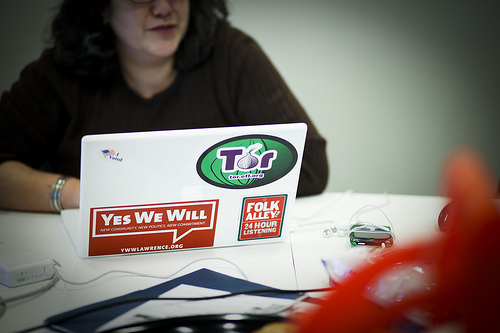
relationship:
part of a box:
[350, 231, 373, 244] [349, 229, 393, 247]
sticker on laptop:
[197, 134, 299, 189] [62, 121, 309, 259]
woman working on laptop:
[0, 0, 332, 213] [62, 121, 309, 259]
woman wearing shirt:
[0, 0, 332, 213] [0, 17, 330, 197]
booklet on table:
[43, 268, 306, 332] [0, 193, 497, 332]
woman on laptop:
[0, 0, 332, 213] [62, 121, 309, 259]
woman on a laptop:
[0, 0, 332, 213] [62, 121, 309, 259]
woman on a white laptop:
[0, 0, 332, 213] [62, 121, 309, 259]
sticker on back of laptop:
[197, 134, 299, 189] [62, 121, 309, 259]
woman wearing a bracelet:
[0, 0, 332, 213] [49, 173, 69, 216]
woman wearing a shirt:
[0, 0, 332, 213] [0, 17, 330, 197]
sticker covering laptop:
[197, 134, 299, 189] [62, 121, 309, 259]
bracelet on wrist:
[49, 173, 69, 216] [39, 172, 77, 216]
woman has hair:
[0, 0, 332, 213] [171, 0, 229, 76]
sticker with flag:
[101, 149, 123, 162] [103, 149, 114, 156]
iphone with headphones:
[349, 229, 393, 247] [322, 222, 394, 268]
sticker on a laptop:
[197, 134, 299, 189] [62, 121, 309, 259]